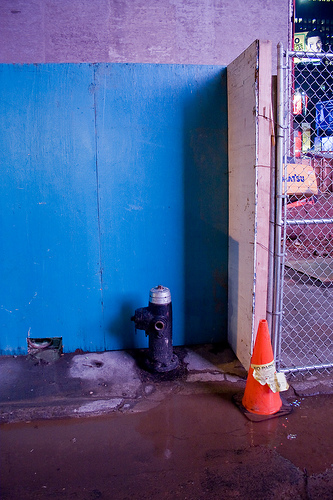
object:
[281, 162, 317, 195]
construction vehicle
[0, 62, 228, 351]
blue wall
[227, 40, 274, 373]
wall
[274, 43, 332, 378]
chain-link fencing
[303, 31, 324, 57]
man's face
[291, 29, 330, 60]
sign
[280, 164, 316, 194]
box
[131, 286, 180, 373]
fire hydrant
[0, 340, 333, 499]
floor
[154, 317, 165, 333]
nozzle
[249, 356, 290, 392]
paper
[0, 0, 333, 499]
building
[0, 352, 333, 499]
cement pavement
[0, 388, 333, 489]
puddle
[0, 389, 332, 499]
water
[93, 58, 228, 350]
plywood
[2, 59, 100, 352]
plywood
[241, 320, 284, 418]
cone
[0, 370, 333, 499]
ground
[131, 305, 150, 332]
nozzle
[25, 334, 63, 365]
gap